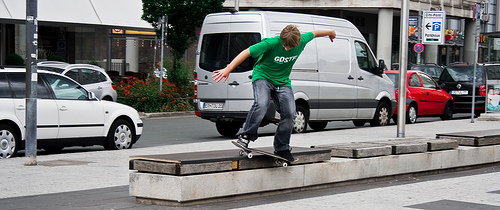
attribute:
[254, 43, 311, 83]
t-shirt — green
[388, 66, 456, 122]
car — red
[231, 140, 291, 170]
skateboard — black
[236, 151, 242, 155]
wheels — white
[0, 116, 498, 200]
sidewalk — grey, cement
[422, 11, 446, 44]
sign — white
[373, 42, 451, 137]
car — red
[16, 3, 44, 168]
pole — metal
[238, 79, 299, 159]
jeans — on photo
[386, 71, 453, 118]
car — red, two door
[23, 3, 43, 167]
pole — dark grey, metal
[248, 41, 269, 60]
sleeve — green, short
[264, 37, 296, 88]
t-shirt — short sleeve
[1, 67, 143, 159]
car — four door, white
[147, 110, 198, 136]
road — side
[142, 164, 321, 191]
bench — street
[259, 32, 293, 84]
shirt — green